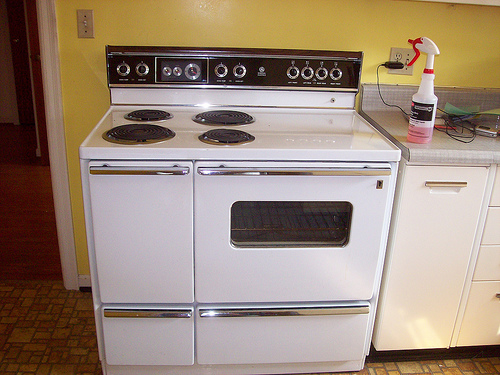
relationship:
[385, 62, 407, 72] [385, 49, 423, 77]
black plug in outlet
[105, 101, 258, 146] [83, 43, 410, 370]
burners on stove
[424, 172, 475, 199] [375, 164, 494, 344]
handle on cabinet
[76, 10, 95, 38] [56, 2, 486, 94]
switch on wall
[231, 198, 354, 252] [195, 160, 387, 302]
window on oven door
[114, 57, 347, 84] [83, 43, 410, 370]
knobs on stove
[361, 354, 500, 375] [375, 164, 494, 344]
tiles near cabinet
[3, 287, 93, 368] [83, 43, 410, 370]
tiles near stove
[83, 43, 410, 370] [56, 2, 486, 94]
stove by wall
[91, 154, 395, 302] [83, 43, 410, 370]
oven on stove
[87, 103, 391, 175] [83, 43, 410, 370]
stove top on stove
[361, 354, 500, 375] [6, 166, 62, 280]
tiles near floor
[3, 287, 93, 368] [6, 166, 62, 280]
tiles near floor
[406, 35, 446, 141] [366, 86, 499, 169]
bottle on counter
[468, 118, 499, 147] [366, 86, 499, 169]
cell phone on counter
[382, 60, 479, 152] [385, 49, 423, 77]
phone charger in outlet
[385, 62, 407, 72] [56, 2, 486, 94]
black plug in wall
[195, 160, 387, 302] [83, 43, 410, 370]
oven door on stove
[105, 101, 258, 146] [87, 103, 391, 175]
burners on stove top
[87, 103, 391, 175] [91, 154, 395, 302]
stove top on oven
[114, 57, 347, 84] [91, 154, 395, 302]
knobs on oven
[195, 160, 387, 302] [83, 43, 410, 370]
oven door under stove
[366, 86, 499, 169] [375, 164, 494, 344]
counter over cabinet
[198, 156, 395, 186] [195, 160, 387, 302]
handle on oven door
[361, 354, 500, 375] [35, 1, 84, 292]
tiles near doorway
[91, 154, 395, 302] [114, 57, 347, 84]
oven has knobs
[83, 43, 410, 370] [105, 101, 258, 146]
stove has burners